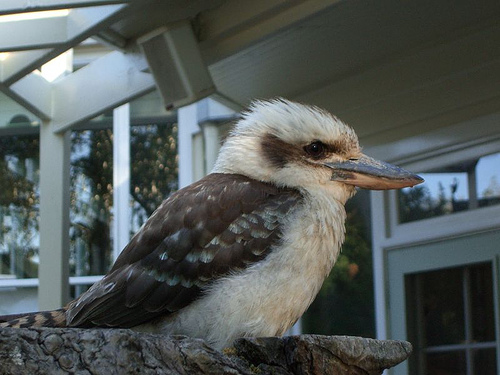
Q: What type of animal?
A: Bird.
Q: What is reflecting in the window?
A: Tree.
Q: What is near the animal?
A: A building.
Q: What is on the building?
A: Windows.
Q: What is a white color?
A: The building.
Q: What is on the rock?
A: A bird.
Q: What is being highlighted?
A: Front part of bird.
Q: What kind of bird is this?
A: A kookaburra.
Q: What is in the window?
A: Reflections.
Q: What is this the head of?
A: A kookaburra.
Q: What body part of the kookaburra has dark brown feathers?
A: The wing.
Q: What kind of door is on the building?
A: A glass paneled door.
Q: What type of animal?
A: Bird.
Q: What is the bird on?
A: Stone wall.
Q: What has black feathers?
A: Bird.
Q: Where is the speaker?
A: Hanging from the roof.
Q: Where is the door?
A: Behind the bird.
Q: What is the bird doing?
A: Sitting on a wall.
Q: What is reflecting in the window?
A: Tree.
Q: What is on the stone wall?
A: Bird.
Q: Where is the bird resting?
A: On the wall.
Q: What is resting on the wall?
A: Bird.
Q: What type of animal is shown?
A: Bird.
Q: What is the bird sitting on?
A: Wood.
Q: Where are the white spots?
A: Wings.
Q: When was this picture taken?
A: During the day.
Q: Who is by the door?
A: Nobody.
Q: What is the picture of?
A: A bird.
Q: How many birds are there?
A: 1.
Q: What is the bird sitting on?
A: A branch.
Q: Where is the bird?
A: On a branch.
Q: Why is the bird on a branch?
A: He is resting.